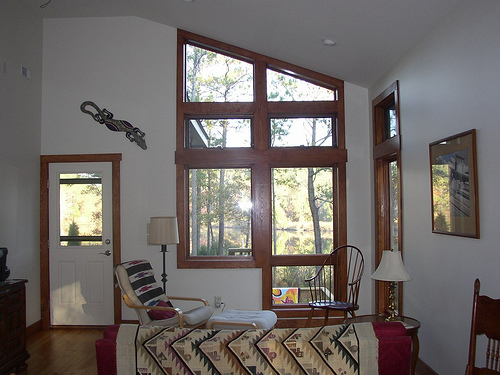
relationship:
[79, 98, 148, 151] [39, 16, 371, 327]
gecko figurine on side of wall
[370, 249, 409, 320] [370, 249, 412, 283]
lamp has lamp shade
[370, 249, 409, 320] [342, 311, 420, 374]
lamp on top of end table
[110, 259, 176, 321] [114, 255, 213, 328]
blanket hanging over chair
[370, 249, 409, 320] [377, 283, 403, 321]
lamp has base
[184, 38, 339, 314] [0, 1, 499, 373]
window inside of living room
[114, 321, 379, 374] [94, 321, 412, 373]
blanket on back of couch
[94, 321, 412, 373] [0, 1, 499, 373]
couch inside of living room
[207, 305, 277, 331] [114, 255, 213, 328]
ottoman in front of chair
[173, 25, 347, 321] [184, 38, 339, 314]
frame around window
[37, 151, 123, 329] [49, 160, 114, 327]
door frame around door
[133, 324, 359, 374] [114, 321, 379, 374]
design part of blanket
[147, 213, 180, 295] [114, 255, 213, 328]
floor lamp behind chair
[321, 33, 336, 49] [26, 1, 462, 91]
recessed light built into ceiling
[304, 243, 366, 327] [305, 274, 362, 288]
chair has arms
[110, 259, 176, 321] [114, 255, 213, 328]
blanket hung over chair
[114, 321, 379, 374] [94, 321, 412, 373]
blanket hung over couch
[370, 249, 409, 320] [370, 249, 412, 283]
lamp with lamp shade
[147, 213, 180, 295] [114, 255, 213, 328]
floor lamp next to chair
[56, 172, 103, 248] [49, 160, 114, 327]
window inside of door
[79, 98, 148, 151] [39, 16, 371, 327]
gecko figurine hanging on wall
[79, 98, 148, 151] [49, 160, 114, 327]
gecko figurine above door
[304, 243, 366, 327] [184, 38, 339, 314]
chair next to window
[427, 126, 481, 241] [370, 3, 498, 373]
picture hanging on wall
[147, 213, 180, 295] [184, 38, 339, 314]
floor lamp next to window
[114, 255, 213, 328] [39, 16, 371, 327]
chair next to wall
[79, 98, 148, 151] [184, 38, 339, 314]
gecko figurine next to window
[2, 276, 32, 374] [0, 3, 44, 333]
chest against wall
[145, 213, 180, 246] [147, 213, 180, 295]
lamp shade on top of floor lamp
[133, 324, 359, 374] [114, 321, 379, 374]
design woven into blanket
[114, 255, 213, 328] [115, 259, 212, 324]
chair has cushion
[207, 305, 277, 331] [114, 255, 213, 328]
ottoman matches chair